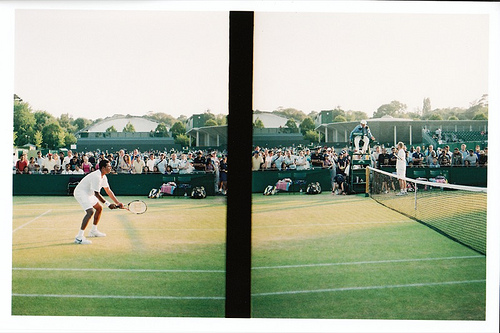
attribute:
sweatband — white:
[101, 190, 125, 213]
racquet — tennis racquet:
[106, 190, 156, 223]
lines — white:
[20, 271, 204, 322]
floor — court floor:
[27, 237, 497, 316]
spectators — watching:
[19, 146, 438, 174]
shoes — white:
[75, 221, 104, 243]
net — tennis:
[367, 165, 486, 236]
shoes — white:
[75, 228, 105, 246]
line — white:
[13, 256, 477, 274]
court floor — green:
[24, 190, 480, 322]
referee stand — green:
[345, 148, 377, 195]